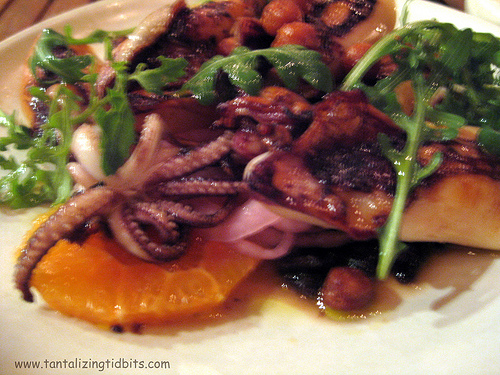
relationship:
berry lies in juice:
[311, 261, 383, 311] [258, 268, 473, 313]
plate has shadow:
[14, 306, 497, 374] [421, 243, 463, 310]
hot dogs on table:
[45, 260, 201, 288] [13, 7, 136, 35]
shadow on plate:
[414, 249, 493, 310] [1, 1, 499, 373]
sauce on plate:
[427, 250, 496, 309] [1, 1, 499, 373]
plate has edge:
[0, 0, 500, 375] [8, 7, 87, 30]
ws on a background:
[11, 360, 42, 370] [2, 341, 495, 375]